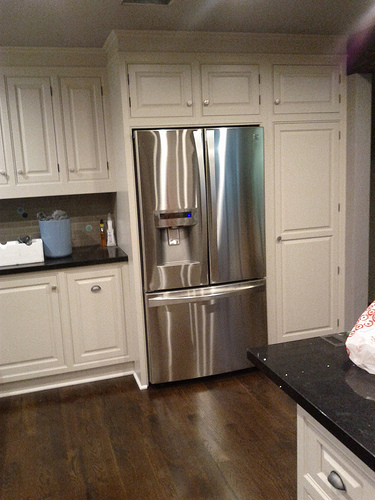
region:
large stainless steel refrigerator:
[125, 126, 287, 389]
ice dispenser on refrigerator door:
[136, 173, 227, 303]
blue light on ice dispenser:
[147, 198, 217, 297]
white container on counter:
[100, 209, 127, 264]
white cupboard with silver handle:
[57, 271, 146, 373]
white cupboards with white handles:
[114, 52, 277, 120]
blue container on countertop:
[22, 202, 86, 277]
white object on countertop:
[1, 232, 59, 279]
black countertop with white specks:
[244, 333, 360, 425]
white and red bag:
[335, 292, 373, 379]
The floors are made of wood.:
[83, 422, 250, 498]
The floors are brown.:
[69, 410, 268, 498]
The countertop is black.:
[279, 348, 340, 386]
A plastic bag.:
[342, 286, 373, 380]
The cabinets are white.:
[274, 74, 343, 311]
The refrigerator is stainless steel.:
[127, 119, 278, 397]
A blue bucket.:
[32, 205, 77, 266]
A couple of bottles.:
[92, 202, 125, 262]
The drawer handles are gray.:
[308, 460, 358, 496]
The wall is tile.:
[76, 201, 100, 243]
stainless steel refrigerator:
[119, 123, 286, 394]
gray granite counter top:
[253, 332, 360, 417]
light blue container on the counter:
[34, 211, 81, 263]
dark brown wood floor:
[68, 406, 216, 490]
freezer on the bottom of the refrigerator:
[133, 259, 292, 391]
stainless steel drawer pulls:
[320, 465, 354, 497]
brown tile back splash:
[2, 220, 38, 235]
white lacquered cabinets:
[2, 65, 113, 191]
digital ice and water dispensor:
[148, 200, 205, 273]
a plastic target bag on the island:
[329, 294, 372, 380]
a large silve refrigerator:
[127, 123, 267, 401]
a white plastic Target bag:
[338, 295, 374, 364]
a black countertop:
[239, 309, 371, 460]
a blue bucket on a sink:
[36, 214, 77, 260]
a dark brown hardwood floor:
[0, 360, 312, 497]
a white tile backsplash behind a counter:
[12, 199, 111, 251]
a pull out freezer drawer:
[132, 274, 274, 391]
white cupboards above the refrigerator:
[124, 61, 272, 118]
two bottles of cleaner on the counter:
[97, 211, 121, 250]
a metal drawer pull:
[321, 465, 349, 490]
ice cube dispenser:
[154, 209, 200, 265]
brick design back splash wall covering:
[0, 212, 117, 246]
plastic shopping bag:
[343, 300, 374, 373]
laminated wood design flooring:
[0, 366, 296, 498]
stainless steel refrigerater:
[132, 125, 268, 384]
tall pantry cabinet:
[272, 117, 342, 342]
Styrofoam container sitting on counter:
[0, 237, 45, 265]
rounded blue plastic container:
[38, 217, 73, 257]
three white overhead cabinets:
[123, 60, 344, 117]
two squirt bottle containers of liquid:
[97, 210, 116, 247]